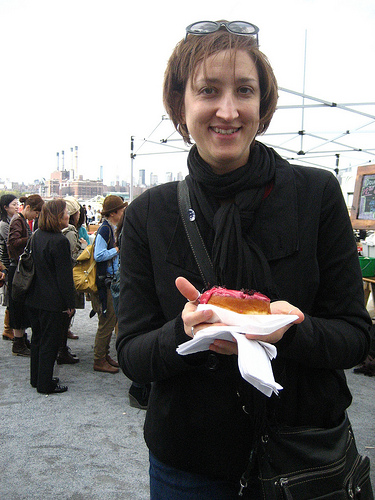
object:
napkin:
[175, 329, 283, 399]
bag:
[234, 411, 372, 497]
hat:
[101, 195, 128, 216]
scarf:
[186, 137, 279, 299]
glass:
[186, 18, 261, 40]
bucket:
[358, 254, 375, 278]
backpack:
[71, 236, 99, 297]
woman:
[110, 13, 371, 500]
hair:
[161, 19, 277, 145]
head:
[162, 20, 277, 167]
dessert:
[198, 285, 272, 317]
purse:
[242, 402, 375, 500]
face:
[184, 49, 261, 159]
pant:
[37, 312, 67, 393]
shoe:
[35, 383, 69, 393]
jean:
[143, 443, 238, 499]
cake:
[198, 285, 272, 315]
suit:
[24, 227, 73, 394]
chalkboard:
[356, 174, 374, 221]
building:
[38, 145, 104, 198]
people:
[24, 194, 75, 400]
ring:
[186, 289, 201, 303]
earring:
[174, 118, 184, 135]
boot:
[92, 351, 120, 375]